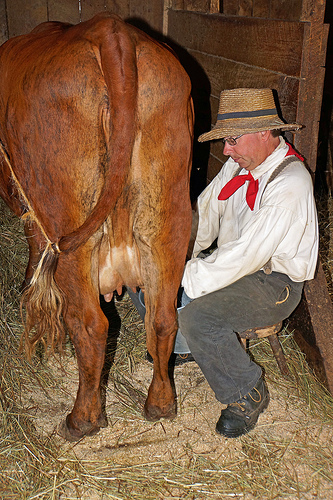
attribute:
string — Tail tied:
[5, 167, 68, 354]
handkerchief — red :
[213, 141, 305, 208]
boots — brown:
[147, 341, 274, 436]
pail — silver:
[138, 285, 194, 354]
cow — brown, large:
[0, 12, 193, 443]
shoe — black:
[145, 348, 193, 364]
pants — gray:
[126, 270, 304, 403]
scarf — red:
[217, 141, 304, 209]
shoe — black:
[214, 373, 268, 435]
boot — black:
[215, 374, 270, 438]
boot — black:
[146, 348, 194, 366]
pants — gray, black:
[125, 247, 303, 402]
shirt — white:
[181, 135, 318, 298]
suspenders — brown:
[225, 154, 302, 274]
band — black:
[213, 105, 283, 121]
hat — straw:
[197, 83, 304, 144]